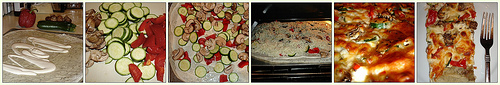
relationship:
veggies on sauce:
[173, 1, 249, 79] [168, 2, 248, 81]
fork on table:
[479, 11, 494, 82] [417, 2, 497, 82]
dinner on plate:
[425, 1, 475, 82] [417, 3, 497, 83]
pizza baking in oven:
[252, 20, 332, 62] [252, 1, 332, 81]